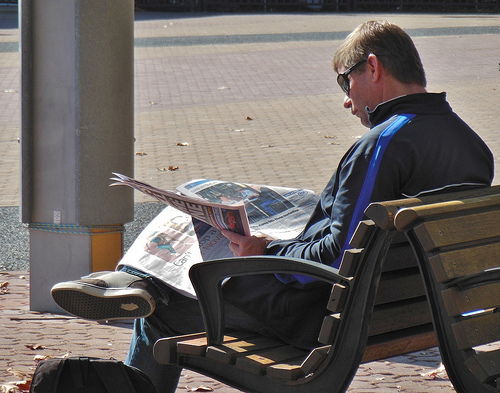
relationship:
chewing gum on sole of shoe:
[120, 304, 139, 311] [54, 288, 149, 319]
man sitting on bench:
[52, 19, 491, 390] [154, 182, 497, 392]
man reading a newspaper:
[52, 19, 491, 390] [109, 169, 320, 300]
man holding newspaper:
[52, 19, 491, 390] [109, 169, 320, 300]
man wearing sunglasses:
[52, 19, 491, 390] [337, 59, 366, 95]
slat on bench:
[414, 211, 499, 250] [154, 182, 497, 392]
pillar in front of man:
[19, 1, 134, 314] [52, 19, 491, 390]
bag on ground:
[31, 358, 154, 392] [1, 0, 499, 391]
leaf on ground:
[189, 387, 213, 392] [1, 0, 499, 391]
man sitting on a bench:
[52, 19, 491, 390] [154, 182, 497, 392]